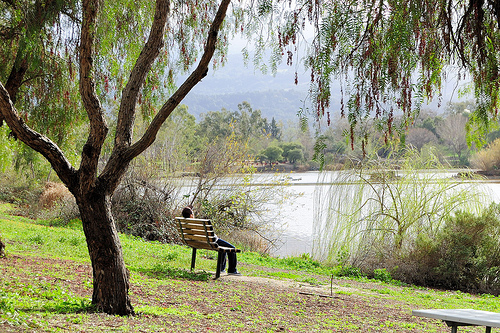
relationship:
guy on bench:
[180, 206, 239, 278] [176, 219, 242, 280]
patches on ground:
[261, 286, 282, 312] [3, 208, 498, 333]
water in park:
[120, 167, 500, 261] [1, 2, 495, 331]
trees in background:
[1, 2, 223, 319] [8, 123, 498, 331]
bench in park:
[176, 219, 242, 280] [1, 2, 495, 331]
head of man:
[182, 205, 197, 217] [180, 206, 239, 278]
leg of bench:
[214, 250, 224, 279] [176, 219, 242, 280]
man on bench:
[180, 206, 239, 278] [176, 219, 242, 280]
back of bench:
[175, 217, 216, 248] [176, 219, 242, 280]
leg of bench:
[191, 249, 200, 267] [176, 219, 242, 280]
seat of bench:
[186, 245, 243, 255] [176, 219, 242, 280]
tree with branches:
[70, 2, 194, 323] [306, 1, 499, 75]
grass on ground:
[3, 223, 310, 268] [3, 208, 498, 333]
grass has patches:
[3, 223, 310, 268] [261, 286, 282, 312]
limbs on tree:
[306, 1, 499, 75] [70, 2, 194, 323]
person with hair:
[180, 206, 239, 278] [185, 207, 190, 215]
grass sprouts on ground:
[211, 289, 223, 297] [3, 208, 498, 333]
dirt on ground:
[255, 274, 291, 288] [3, 208, 498, 333]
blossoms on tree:
[387, 109, 396, 130] [70, 2, 194, 323]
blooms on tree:
[419, 33, 437, 65] [70, 2, 194, 323]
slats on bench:
[188, 226, 204, 237] [176, 219, 242, 280]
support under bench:
[214, 250, 224, 279] [176, 219, 242, 280]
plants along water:
[120, 167, 500, 261] [214, 170, 428, 236]